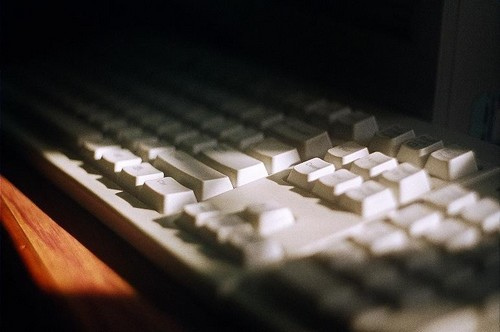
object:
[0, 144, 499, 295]
light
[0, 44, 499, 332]
keyboard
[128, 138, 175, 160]
keys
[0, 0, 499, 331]
table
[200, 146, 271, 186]
button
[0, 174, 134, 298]
sun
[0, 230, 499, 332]
shadow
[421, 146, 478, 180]
shadows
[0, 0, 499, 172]
dark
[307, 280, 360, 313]
sunshine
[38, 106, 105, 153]
space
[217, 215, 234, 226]
arrows